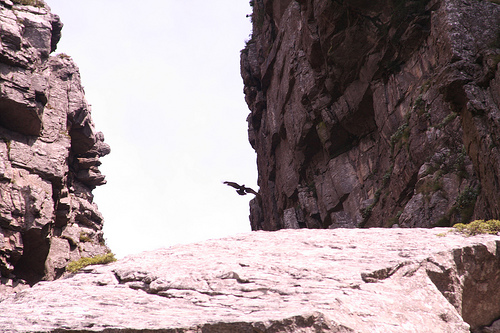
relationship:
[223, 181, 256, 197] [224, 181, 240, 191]
bird has a wing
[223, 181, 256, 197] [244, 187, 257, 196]
bird has a wing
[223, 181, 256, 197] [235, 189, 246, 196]
bird has a tail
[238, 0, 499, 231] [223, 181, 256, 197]
rock by bird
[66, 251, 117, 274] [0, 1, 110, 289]
grass in front of rock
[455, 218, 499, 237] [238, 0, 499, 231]
grass in front of rock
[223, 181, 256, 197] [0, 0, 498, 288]
bird between rocks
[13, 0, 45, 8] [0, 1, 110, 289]
plant on rock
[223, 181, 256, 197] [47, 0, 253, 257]
bird in sky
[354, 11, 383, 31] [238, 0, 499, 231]
crack in rock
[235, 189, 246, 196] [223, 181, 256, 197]
tail on bird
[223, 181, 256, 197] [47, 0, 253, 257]
bird flying in sky